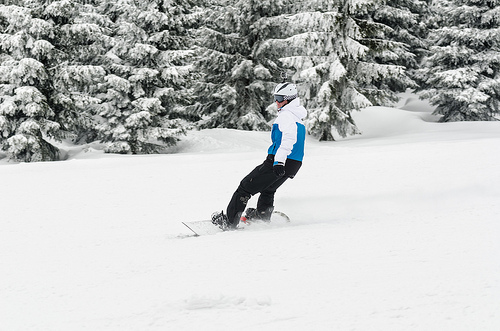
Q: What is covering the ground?
A: Snow.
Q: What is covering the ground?
A: Snow.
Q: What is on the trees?
A: Snow.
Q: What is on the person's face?
A: Goggles.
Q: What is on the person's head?
A: Helmet.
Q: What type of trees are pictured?
A: Evergreen.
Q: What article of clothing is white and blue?
A: Jacket.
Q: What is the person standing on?
A: Snow board.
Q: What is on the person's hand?
A: Glove.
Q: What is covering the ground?
A: Snow.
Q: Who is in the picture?
A: A skier.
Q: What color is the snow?
A: White.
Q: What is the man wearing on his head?
A: Helmet.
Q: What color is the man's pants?
A: Black.